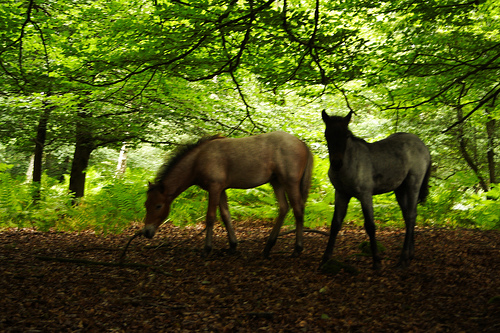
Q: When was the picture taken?
A: Daylight.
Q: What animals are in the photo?
A: Donkeys.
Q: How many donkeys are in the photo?
A: 2.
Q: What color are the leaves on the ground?
A: Brown.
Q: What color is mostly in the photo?
A: Green.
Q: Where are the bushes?
A: Behind the donkeys.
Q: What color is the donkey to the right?
A: Gray.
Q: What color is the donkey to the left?
A: Brown.